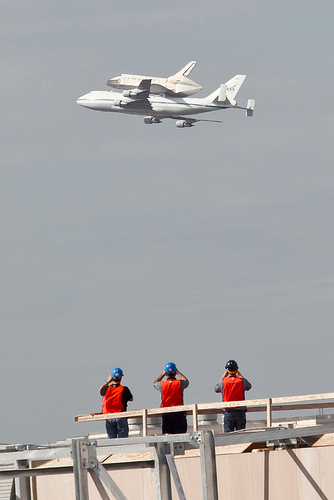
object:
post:
[203, 432, 217, 499]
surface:
[0, 428, 334, 499]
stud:
[198, 433, 203, 440]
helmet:
[164, 362, 178, 377]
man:
[154, 360, 190, 433]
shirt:
[159, 380, 183, 407]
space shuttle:
[107, 58, 203, 98]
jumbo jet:
[76, 59, 255, 129]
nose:
[108, 75, 120, 88]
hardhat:
[224, 358, 238, 374]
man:
[215, 358, 253, 432]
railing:
[74, 391, 333, 425]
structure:
[0, 426, 323, 500]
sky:
[0, 1, 334, 444]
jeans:
[105, 416, 128, 438]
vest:
[101, 386, 126, 416]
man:
[99, 366, 135, 439]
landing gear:
[143, 106, 195, 127]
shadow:
[281, 441, 329, 499]